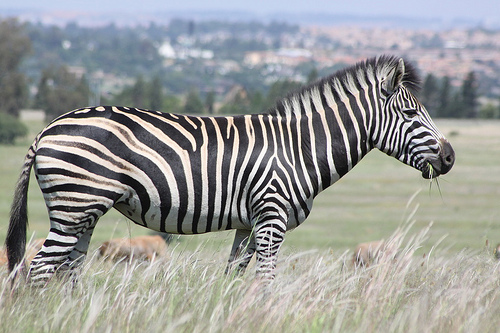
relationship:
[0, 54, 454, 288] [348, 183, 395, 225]
zebra in a field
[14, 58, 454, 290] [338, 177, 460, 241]
zebra eating grass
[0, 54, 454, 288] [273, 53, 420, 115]
zebra with hair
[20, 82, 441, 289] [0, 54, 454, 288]
stripe on zebra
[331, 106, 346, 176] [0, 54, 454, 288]
black stripe on zebra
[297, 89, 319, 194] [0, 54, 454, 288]
stripe on zebra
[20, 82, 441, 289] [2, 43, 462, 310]
stripe on zebra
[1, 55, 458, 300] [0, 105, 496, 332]
animal are in grass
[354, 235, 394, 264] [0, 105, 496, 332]
animal are in grass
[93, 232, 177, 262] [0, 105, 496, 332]
animal are in grass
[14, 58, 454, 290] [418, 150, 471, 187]
zebra eating grass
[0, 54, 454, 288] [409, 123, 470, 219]
zebra with nose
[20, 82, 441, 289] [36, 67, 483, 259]
stripe on zebra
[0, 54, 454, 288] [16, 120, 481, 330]
zebra in field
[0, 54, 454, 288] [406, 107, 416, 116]
zebra has eye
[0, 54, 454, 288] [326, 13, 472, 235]
zebra has head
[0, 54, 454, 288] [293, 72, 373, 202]
zebra has neck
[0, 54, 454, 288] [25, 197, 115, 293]
zebra has back leg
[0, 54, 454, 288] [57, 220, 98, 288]
zebra has back leg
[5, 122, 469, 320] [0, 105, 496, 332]
field has grass